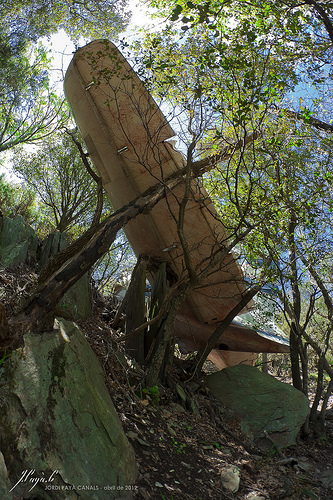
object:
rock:
[61, 40, 253, 338]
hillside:
[2, 220, 328, 500]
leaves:
[304, 452, 310, 458]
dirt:
[159, 457, 329, 499]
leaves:
[124, 410, 131, 423]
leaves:
[37, 230, 43, 238]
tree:
[282, 6, 329, 438]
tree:
[136, 0, 254, 384]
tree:
[31, 134, 243, 324]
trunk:
[20, 243, 93, 311]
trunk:
[78, 148, 106, 230]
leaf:
[323, 269, 328, 275]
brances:
[293, 247, 300, 257]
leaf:
[315, 166, 319, 171]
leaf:
[312, 174, 316, 179]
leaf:
[316, 198, 320, 207]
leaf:
[265, 177, 268, 183]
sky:
[2, 1, 329, 45]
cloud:
[134, 5, 150, 32]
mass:
[143, 383, 160, 399]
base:
[148, 342, 174, 375]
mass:
[176, 385, 188, 402]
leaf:
[158, 443, 165, 448]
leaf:
[229, 456, 235, 462]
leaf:
[190, 417, 195, 422]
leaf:
[205, 486, 212, 496]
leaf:
[161, 435, 167, 442]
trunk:
[148, 286, 186, 380]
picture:
[4, 1, 331, 500]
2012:
[126, 485, 138, 492]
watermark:
[8, 466, 150, 499]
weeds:
[103, 285, 111, 295]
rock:
[221, 467, 240, 494]